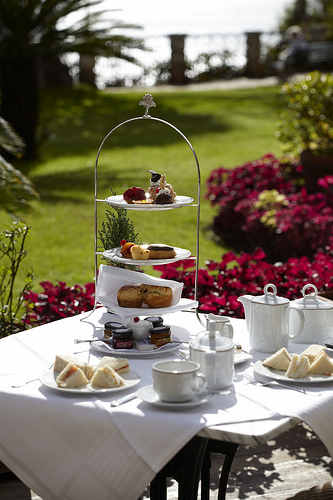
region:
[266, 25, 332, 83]
person sitting on a bench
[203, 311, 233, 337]
small white creamer server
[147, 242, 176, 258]
round doughnut with chocolate icing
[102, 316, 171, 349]
four small jars of jelly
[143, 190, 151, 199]
sunshine reflecting off serving platter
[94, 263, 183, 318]
white cloth underneath pastries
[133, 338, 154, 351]
small butter container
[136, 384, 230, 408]
small round saucer with a spoon on it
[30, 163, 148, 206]
shadow of a tree in the grass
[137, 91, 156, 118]
silver decorative piece on top of tray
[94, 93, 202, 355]
a tiered metal pastry display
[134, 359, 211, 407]
white coffee cup on saucer on edge of the table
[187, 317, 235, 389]
white pot with lid near coffee cup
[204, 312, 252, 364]
white creamer on behind the pot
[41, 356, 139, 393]
a plate with sandwiches on the left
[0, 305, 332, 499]
a table with a white tablecloth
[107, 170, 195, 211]
pastries on white plate on top tier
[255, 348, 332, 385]
plate with a sandwich on the right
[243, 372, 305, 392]
a silver fork on the right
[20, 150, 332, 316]
red flowers behind the table.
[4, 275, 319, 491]
table with dishes on it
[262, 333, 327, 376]
plate with sandwiches on it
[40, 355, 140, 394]
plate with sandwiches on it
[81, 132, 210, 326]
stand with multiple levels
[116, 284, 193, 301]
pastries on shelf of stand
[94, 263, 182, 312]
napkin pastries on are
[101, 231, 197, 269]
platter with pastries on it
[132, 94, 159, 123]
decorative piece on top of stand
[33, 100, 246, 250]
lawn of green space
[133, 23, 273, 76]
fence in the back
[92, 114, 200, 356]
rack with four plates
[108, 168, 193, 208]
desserts on white plate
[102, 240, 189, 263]
three pastries on plate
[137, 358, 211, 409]
white cup on saucer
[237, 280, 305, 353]
white pot with handle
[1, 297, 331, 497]
white cloth on table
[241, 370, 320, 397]
fork on white cloth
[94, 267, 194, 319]
white cloth over muffins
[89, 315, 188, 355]
four jars on a plate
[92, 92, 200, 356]
pastries on a serving tray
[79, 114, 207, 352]
silver tiered rack with pastries on it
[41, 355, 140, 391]
cut pieces of a sandwich on a plate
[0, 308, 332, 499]
white tablecloth draped over table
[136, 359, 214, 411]
white coffee cup on a saucer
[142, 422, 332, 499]
shadows of trees on the ground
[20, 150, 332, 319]
red bushes in landscaping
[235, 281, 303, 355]
white ceramic coffee server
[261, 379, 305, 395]
silver fork laying upside down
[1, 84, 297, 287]
green grassy lawn